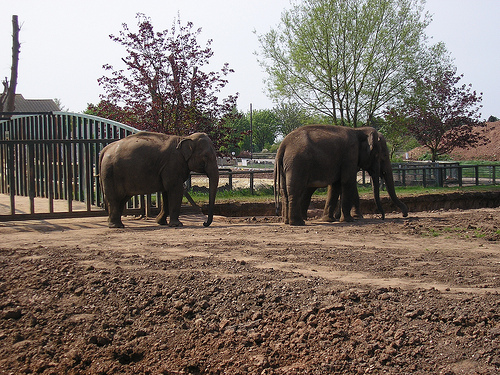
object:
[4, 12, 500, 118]
sky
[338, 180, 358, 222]
leg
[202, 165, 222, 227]
trunk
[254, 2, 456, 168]
tree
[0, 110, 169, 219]
fence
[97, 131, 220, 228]
elephant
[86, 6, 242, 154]
tree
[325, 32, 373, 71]
part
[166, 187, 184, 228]
legs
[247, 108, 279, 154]
tree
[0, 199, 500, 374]
soil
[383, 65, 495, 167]
tree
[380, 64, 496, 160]
leaves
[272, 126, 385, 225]
elephant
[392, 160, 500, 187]
fence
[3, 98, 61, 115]
brown roof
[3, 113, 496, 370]
enclosure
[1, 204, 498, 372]
dirt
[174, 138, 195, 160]
ear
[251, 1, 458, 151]
leaves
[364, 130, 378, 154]
ear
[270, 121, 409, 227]
elephant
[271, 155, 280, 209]
tail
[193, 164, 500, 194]
wooden post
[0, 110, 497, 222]
elephant enclosure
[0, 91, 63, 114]
roof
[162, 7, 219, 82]
leaves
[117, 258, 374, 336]
floor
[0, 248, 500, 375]
ground